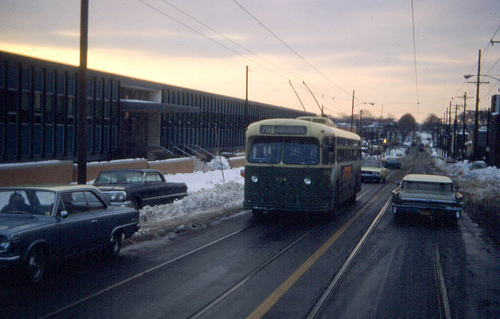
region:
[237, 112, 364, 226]
a yellow and green trolley car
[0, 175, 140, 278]
a car on street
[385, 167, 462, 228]
a car driving on street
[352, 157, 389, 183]
a car driving on street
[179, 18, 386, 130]
overhead power transmission lines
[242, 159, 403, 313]
a long yellow stripe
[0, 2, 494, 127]
a cloudy grey sky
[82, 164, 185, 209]
a parked dark car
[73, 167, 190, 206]
a snowed in parked car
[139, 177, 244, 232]
a large snow bank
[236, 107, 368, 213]
bus on icy street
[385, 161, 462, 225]
car on black street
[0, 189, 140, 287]
car on black street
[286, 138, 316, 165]
front window of bus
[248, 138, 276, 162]
front window of bus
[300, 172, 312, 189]
head light of bus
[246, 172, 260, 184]
head light of bus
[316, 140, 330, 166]
side window of bus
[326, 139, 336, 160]
side window of bus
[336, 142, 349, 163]
side window of bus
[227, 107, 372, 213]
THE BUS IS GREEN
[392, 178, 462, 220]
THE CAR IS BLUE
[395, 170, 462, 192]
THE CAR HAS A WHITE ROOF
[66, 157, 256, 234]
THE SNOW IS PILLED UP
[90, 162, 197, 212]
THE CAR IS BLACK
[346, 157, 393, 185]
THE CAR IS YELLOW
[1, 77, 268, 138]
THE BUILDING HAS MANY WINDOWS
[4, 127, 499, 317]
THE ROAD IS WET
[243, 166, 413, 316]
THE ROAD HAS A YELLOW LINE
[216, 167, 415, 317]
THE LINE IS PAINTED ON THE ROAD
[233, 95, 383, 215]
a bus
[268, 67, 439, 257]
a bus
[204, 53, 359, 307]
a bus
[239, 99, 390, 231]
Green and Yellow Trolley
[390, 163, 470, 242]
Car driving down the street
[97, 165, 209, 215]
Car with snow in front of it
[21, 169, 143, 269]
Blue car driving down the street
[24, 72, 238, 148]
Blue and Yellow factory building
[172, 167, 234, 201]
Snow piled up on the ground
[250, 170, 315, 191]
Headlights on a trolley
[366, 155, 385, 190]
Car behind a trolley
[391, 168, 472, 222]
Car next to a trolley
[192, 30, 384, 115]
Electric lines above a trolley